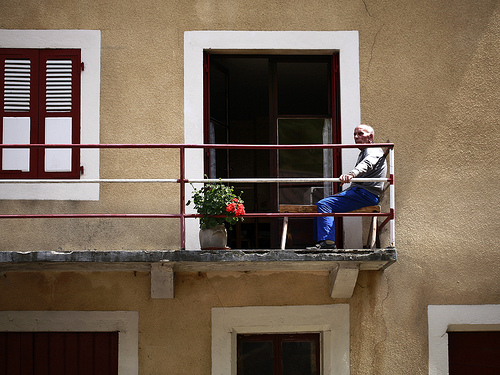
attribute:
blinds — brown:
[1, 29, 97, 187]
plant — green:
[176, 172, 247, 257]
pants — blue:
[309, 184, 383, 250]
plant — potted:
[178, 177, 245, 247]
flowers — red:
[224, 198, 246, 217]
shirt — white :
[346, 146, 386, 189]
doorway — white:
[170, 31, 387, 248]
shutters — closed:
[0, 46, 84, 181]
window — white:
[1, 15, 105, 198]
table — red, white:
[0, 41, 90, 185]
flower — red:
[190, 182, 265, 224]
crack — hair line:
[363, 0, 385, 77]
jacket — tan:
[344, 146, 386, 193]